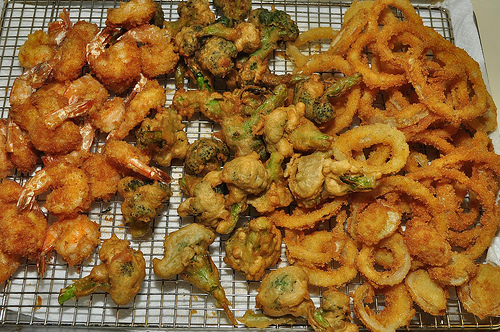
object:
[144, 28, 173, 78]
shrimp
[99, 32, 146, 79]
shrimp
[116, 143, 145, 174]
shrimp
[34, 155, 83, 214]
shrimp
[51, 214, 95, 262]
shrimp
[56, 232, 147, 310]
broccoli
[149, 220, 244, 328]
broccoli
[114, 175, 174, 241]
broccoli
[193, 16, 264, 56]
broccoli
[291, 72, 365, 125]
broccoli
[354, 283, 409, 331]
onion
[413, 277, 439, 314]
onion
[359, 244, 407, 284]
onion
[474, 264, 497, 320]
onion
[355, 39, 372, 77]
onion